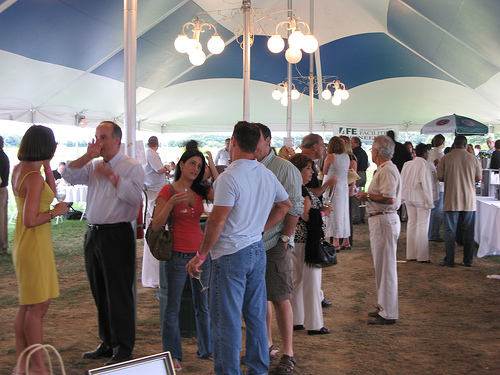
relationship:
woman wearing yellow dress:
[12, 125, 69, 373] [11, 168, 63, 310]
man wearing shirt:
[55, 114, 157, 362] [55, 152, 144, 223]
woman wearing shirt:
[146, 148, 222, 373] [154, 185, 205, 251]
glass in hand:
[185, 257, 210, 300] [184, 251, 206, 277]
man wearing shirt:
[185, 118, 293, 374] [261, 154, 303, 246]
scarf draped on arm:
[307, 207, 324, 264] [304, 192, 332, 221]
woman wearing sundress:
[7, 125, 69, 373] [12, 171, 60, 302]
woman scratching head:
[150, 148, 223, 354] [173, 148, 205, 187]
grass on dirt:
[0, 215, 85, 251] [0, 240, 495, 373]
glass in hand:
[185, 257, 210, 300] [180, 251, 210, 274]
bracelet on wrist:
[169, 236, 233, 273] [192, 250, 210, 263]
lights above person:
[160, 0, 353, 111] [355, 132, 406, 325]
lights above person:
[160, 0, 353, 111] [181, 118, 296, 373]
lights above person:
[160, 0, 353, 111] [10, 119, 77, 374]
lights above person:
[160, 0, 353, 111] [60, 117, 147, 364]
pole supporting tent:
[119, 3, 145, 171] [6, 8, 483, 128]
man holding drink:
[217, 118, 274, 361] [185, 258, 212, 297]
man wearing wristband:
[185, 118, 293, 374] [194, 253, 204, 263]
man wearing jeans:
[185, 118, 293, 374] [208, 242, 271, 372]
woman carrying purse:
[146, 148, 222, 373] [138, 219, 183, 258]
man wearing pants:
[55, 114, 150, 362] [84, 222, 136, 345]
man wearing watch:
[176, 116, 316, 363] [365, 192, 372, 202]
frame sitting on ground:
[87, 344, 169, 374] [3, 249, 481, 373]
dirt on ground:
[390, 332, 492, 374] [394, 262, 498, 374]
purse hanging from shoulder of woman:
[139, 199, 190, 260] [136, 156, 251, 311]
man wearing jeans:
[185, 118, 293, 374] [202, 243, 274, 373]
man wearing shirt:
[185, 118, 293, 374] [205, 159, 291, 266]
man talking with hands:
[185, 118, 293, 374] [82, 136, 115, 177]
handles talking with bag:
[7, 340, 68, 373] [13, 343, 64, 373]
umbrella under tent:
[419, 111, 491, 136] [6, 8, 483, 128]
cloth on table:
[473, 197, 498, 250] [464, 177, 496, 267]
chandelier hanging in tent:
[181, 24, 382, 73] [6, 8, 483, 128]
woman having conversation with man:
[146, 148, 222, 373] [185, 118, 293, 374]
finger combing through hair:
[166, 184, 197, 215] [151, 122, 231, 203]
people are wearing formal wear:
[294, 134, 405, 338] [363, 158, 401, 320]